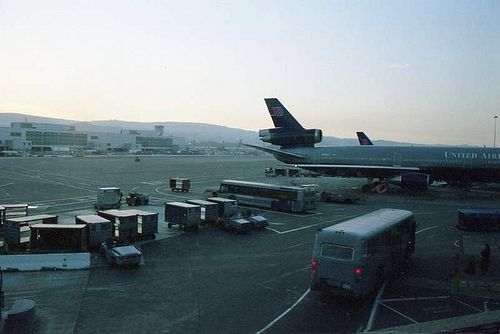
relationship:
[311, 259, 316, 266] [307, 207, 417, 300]
tail light of bus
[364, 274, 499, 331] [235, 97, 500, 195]
lines on plane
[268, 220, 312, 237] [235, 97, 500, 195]
lines on plane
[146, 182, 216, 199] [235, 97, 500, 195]
lines on plane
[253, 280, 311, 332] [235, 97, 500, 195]
lines on plane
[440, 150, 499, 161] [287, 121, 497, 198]
writing on plane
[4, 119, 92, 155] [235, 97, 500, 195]
building on plane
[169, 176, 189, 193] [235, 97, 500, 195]
cart on plane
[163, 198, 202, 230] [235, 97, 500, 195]
cart on plane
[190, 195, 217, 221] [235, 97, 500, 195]
cart on plane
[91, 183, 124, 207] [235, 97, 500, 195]
cart on plane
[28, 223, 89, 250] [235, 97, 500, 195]
cart on plane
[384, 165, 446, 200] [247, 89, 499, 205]
engine on plane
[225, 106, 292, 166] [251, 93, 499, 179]
tail of plane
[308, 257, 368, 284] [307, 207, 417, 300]
lights on bus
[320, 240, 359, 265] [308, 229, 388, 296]
window on bus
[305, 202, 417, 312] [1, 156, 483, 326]
bus on runway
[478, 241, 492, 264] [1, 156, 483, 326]
people standing on runway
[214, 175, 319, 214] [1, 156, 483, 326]
bus on runway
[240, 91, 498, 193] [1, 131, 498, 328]
plane on runway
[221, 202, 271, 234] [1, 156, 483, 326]
trucks on runway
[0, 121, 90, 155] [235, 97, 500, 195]
building behind plane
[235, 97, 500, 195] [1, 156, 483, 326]
plane on runway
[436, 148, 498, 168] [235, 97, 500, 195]
writing on plane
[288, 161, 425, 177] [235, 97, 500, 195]
wing of plane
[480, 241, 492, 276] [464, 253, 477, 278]
people waiting on people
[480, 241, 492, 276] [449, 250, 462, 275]
people waiting on people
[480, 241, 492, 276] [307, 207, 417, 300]
people waiting on bus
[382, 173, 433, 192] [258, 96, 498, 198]
engine of airplane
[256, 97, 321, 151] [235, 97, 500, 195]
tail of plane